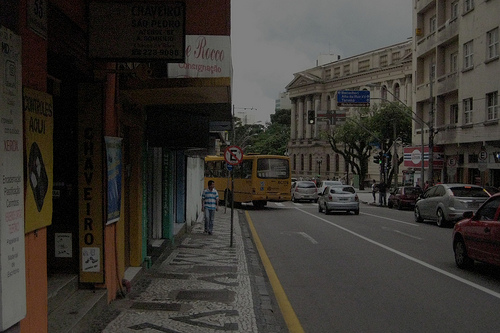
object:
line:
[242, 200, 310, 332]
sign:
[222, 144, 245, 165]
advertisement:
[21, 91, 55, 232]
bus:
[204, 152, 291, 207]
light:
[308, 110, 315, 125]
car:
[451, 194, 500, 273]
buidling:
[412, 27, 488, 146]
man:
[200, 180, 219, 235]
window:
[461, 40, 472, 70]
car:
[318, 185, 360, 216]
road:
[242, 208, 500, 332]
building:
[410, 4, 500, 150]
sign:
[332, 88, 371, 106]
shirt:
[202, 189, 220, 210]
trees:
[343, 102, 415, 194]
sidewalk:
[355, 203, 393, 221]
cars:
[415, 184, 493, 228]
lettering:
[129, 1, 184, 56]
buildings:
[285, 39, 426, 188]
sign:
[24, 90, 57, 235]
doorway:
[36, 74, 111, 333]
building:
[73, 0, 228, 290]